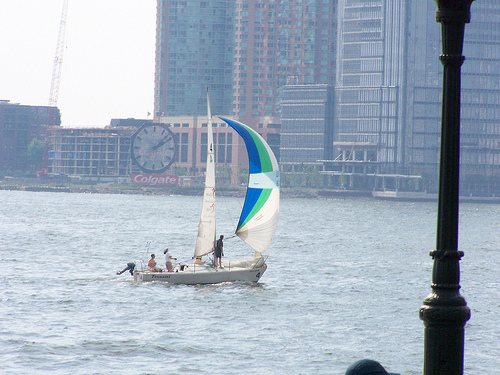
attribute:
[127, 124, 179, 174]
clock — round, large, in the picture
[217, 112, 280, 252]
sail — blue, blue white green, puffed out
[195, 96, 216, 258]
sail — white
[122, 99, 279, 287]
sailboat — white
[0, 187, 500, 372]
water — gray, calm, here, blue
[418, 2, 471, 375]
lamp post — black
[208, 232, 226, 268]
man — caucasian, standing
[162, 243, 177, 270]
woman — caucasian, standing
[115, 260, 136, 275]
engine — metal, black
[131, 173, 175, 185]
sign — red, for colgate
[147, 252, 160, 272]
person — caucasian, shirtless